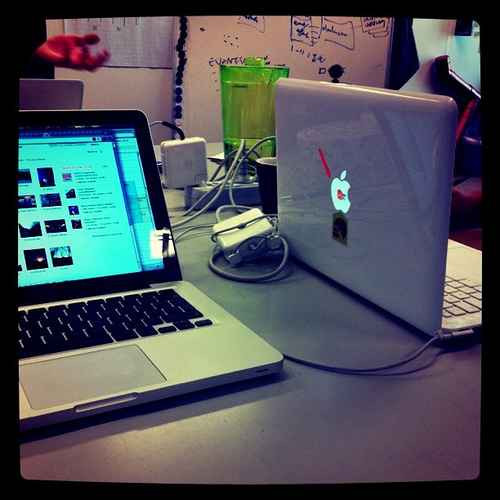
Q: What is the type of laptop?
A: A Apple.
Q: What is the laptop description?
A: Black and Silver.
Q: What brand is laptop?
A: Apple.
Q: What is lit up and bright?
A: Screen.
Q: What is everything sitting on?
A: Table.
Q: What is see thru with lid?
A: Pitcher.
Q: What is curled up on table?
A: Cords.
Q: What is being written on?
A: Board.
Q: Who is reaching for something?
A: A man.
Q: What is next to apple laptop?
A: Cup.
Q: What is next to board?
A: Chart.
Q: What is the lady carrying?
A: Laptop.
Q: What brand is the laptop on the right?
A: Apple.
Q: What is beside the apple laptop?
A: Green jug.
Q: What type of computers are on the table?
A: Laptops.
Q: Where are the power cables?
A: On table.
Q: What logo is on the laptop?
A: Apple.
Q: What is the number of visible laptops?
A: Two.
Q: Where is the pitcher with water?
A: Behind the laptop on the right.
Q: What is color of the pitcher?
A: Green.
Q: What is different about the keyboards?
A: The color.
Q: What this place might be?
A: An office.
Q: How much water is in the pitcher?
A: Less than half.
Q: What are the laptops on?
A: A table.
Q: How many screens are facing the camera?
A: 1.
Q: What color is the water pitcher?
A: Green.